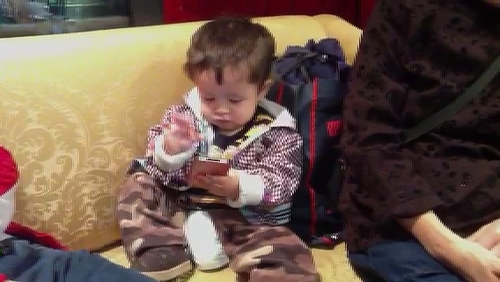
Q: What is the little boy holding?
A: Cell phone.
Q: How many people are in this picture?
A: 2.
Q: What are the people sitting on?
A: Couch.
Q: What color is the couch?
A: Yellow.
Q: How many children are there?
A: 1.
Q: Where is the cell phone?
A: In the boy's hand.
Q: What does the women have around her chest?
A: Purse strap.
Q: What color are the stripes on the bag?
A: Red.